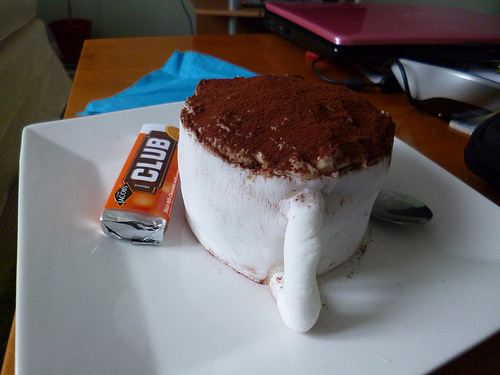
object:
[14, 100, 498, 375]
plate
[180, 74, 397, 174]
chocolate powder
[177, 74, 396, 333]
dessert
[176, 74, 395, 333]
cup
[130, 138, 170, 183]
club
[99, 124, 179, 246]
bar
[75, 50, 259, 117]
napkin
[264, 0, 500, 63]
laptop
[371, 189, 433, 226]
spoon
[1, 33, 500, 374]
table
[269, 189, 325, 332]
handle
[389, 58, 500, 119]
mouse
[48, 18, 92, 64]
flower pot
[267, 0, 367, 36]
shadow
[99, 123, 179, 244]
chocolate bar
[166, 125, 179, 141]
orange